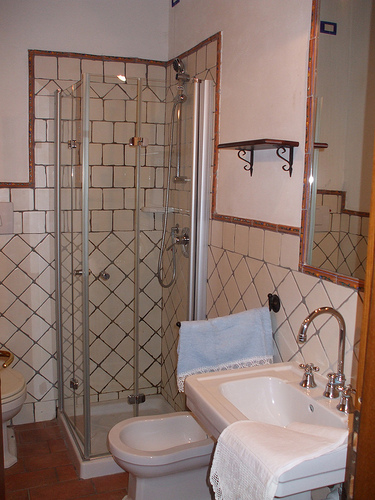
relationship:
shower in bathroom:
[57, 58, 213, 481] [1, 1, 374, 500]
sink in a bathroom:
[182, 360, 348, 497] [1, 1, 374, 500]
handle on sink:
[299, 362, 320, 389] [182, 360, 348, 497]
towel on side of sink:
[210, 419, 350, 499] [182, 360, 348, 497]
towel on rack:
[176, 308, 277, 392] [178, 292, 281, 329]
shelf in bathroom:
[217, 138, 299, 175] [1, 1, 374, 500]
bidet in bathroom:
[107, 410, 219, 500] [1, 1, 374, 500]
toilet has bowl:
[1, 351, 28, 469] [1, 386, 28, 420]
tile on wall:
[248, 225, 266, 263] [161, 1, 373, 409]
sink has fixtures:
[182, 360, 348, 497] [295, 306, 357, 414]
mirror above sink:
[299, 1, 375, 291] [182, 360, 348, 497]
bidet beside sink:
[107, 410, 219, 500] [182, 360, 348, 497]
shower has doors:
[57, 58, 213, 481] [65, 81, 83, 452]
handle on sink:
[337, 384, 357, 414] [182, 360, 348, 497]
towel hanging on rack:
[176, 308, 277, 392] [178, 292, 281, 329]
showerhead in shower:
[171, 59, 184, 73] [57, 58, 213, 481]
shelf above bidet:
[217, 138, 299, 175] [107, 410, 219, 500]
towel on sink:
[210, 419, 350, 499] [182, 360, 348, 497]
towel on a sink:
[210, 419, 350, 499] [182, 360, 348, 497]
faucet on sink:
[295, 306, 348, 398] [182, 360, 348, 497]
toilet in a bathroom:
[1, 351, 28, 469] [1, 1, 374, 500]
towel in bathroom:
[176, 308, 277, 392] [1, 1, 374, 500]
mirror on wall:
[299, 1, 375, 291] [161, 1, 373, 409]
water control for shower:
[167, 227, 190, 255] [57, 58, 213, 481]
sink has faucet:
[182, 360, 348, 497] [295, 306, 348, 398]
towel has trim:
[210, 419, 350, 499] [208, 467, 227, 500]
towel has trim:
[176, 308, 277, 392] [175, 356, 276, 395]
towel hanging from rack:
[176, 308, 277, 392] [178, 292, 281, 329]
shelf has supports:
[217, 138, 299, 175] [235, 143, 295, 177]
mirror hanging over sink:
[299, 1, 375, 291] [182, 360, 348, 497]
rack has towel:
[178, 292, 281, 329] [176, 308, 277, 392]